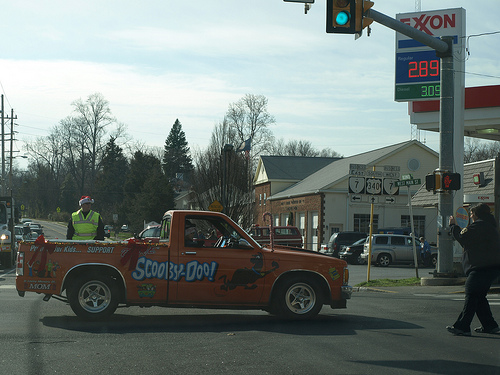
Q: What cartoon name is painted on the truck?
A: Scooby Doo.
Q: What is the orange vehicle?
A: Truck.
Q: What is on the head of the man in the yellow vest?
A: Red hat.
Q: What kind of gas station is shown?
A: Exxon.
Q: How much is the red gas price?
A: 2.89.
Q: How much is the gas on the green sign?
A: 3.09.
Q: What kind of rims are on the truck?
A: Chrome.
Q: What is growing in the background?
A: Tree.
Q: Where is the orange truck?
A: Crossing the road.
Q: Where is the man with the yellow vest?
A: Behind the truck.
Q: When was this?
A: Daytime.